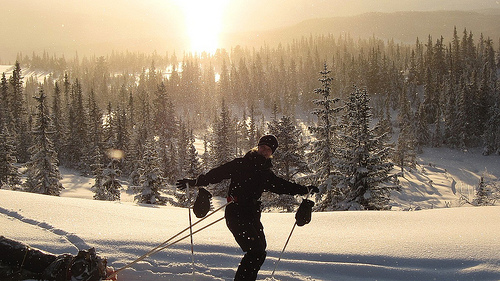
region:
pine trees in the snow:
[18, 51, 481, 207]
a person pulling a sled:
[185, 137, 325, 272]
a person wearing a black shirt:
[212, 135, 284, 275]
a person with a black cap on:
[209, 143, 307, 268]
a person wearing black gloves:
[190, 134, 324, 278]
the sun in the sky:
[139, 1, 277, 59]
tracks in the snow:
[48, 233, 286, 272]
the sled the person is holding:
[18, 234, 118, 278]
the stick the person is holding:
[275, 163, 336, 273]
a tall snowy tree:
[307, 63, 349, 183]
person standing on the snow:
[172, 121, 330, 279]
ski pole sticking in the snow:
[175, 173, 212, 276]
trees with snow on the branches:
[4, 59, 421, 216]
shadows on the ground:
[110, 238, 497, 280]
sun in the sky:
[179, 18, 227, 63]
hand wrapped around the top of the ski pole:
[304, 178, 322, 198]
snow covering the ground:
[2, 66, 499, 280]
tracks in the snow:
[110, 253, 226, 280]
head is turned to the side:
[247, 129, 279, 160]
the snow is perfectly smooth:
[46, 193, 478, 261]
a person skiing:
[179, 127, 315, 279]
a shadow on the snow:
[319, 252, 368, 278]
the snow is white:
[367, 204, 444, 248]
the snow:
[385, 211, 480, 248]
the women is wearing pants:
[226, 218, 264, 280]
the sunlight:
[180, 19, 228, 51]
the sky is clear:
[30, 12, 86, 38]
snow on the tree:
[305, 108, 352, 178]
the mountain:
[327, 17, 397, 28]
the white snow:
[50, 203, 134, 231]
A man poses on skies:
[175, 129, 303, 279]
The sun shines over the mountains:
[174, 3, 239, 52]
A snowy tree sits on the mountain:
[26, 86, 63, 198]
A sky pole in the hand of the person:
[177, 183, 197, 278]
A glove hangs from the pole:
[296, 195, 313, 233]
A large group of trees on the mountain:
[7, 36, 497, 219]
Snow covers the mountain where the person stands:
[6, 201, 498, 280]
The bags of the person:
[0, 234, 119, 276]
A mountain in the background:
[155, 5, 499, 40]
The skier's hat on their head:
[260, 133, 280, 150]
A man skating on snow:
[193, 129, 315, 278]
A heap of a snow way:
[360, 229, 490, 279]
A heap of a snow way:
[83, 195, 162, 260]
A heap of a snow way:
[8, 188, 98, 251]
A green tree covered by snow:
[346, 91, 403, 221]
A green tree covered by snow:
[313, 70, 344, 199]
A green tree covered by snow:
[29, 88, 71, 196]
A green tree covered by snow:
[136, 138, 181, 210]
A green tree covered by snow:
[94, 152, 122, 197]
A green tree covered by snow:
[81, 90, 114, 178]